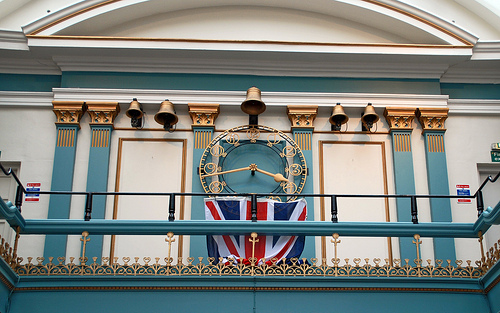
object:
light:
[328, 102, 349, 126]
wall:
[1, 5, 499, 270]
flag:
[204, 196, 307, 267]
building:
[1, 0, 497, 310]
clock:
[199, 124, 307, 200]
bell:
[125, 98, 144, 120]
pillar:
[38, 120, 77, 265]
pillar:
[79, 123, 115, 263]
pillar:
[188, 127, 214, 267]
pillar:
[291, 129, 316, 259]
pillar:
[391, 129, 421, 266]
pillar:
[421, 129, 456, 266]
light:
[241, 85, 267, 116]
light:
[361, 102, 379, 126]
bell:
[328, 104, 349, 126]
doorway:
[0, 159, 21, 249]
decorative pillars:
[163, 229, 176, 268]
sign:
[490, 143, 500, 163]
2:
[281, 145, 297, 158]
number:
[245, 129, 260, 145]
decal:
[115, 137, 189, 267]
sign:
[454, 183, 475, 203]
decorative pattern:
[1, 232, 500, 278]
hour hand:
[253, 163, 289, 183]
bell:
[240, 86, 266, 116]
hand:
[202, 163, 249, 177]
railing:
[0, 167, 500, 248]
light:
[126, 100, 144, 119]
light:
[154, 99, 179, 126]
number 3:
[289, 163, 304, 177]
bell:
[154, 99, 179, 126]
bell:
[359, 101, 378, 125]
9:
[204, 162, 217, 174]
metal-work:
[198, 153, 223, 173]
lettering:
[464, 134, 484, 160]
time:
[204, 163, 296, 185]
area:
[0, 242, 491, 310]